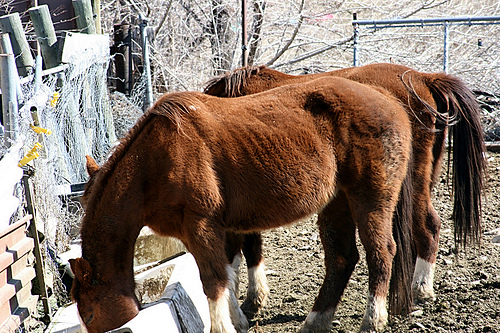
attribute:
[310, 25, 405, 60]
fence — grey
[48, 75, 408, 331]
horse — brown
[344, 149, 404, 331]
leg — brown, white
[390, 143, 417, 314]
tail — brown